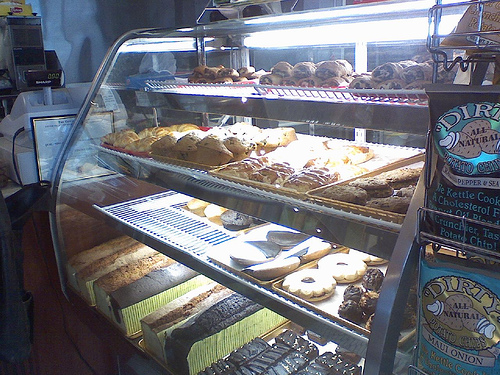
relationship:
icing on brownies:
[278, 340, 316, 372] [282, 332, 317, 359]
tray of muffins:
[156, 119, 304, 173] [149, 120, 298, 170]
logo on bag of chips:
[412, 253, 497, 374] [411, 250, 498, 364]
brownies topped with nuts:
[282, 332, 317, 359] [284, 327, 357, 373]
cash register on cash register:
[0, 68, 144, 185] [0, 68, 144, 185]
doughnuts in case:
[71, 64, 451, 372] [36, 3, 483, 364]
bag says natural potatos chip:
[425, 92, 499, 248] [434, 105, 499, 177]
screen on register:
[22, 66, 65, 90] [0, 68, 144, 185]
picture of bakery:
[1, 1, 499, 374] [71, 64, 451, 372]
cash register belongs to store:
[0, 68, 144, 185] [1, 1, 499, 374]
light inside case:
[229, 17, 469, 54] [36, 3, 483, 364]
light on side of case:
[123, 30, 229, 55] [36, 3, 483, 364]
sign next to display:
[28, 108, 124, 188] [36, 3, 483, 364]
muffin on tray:
[195, 136, 230, 167] [156, 119, 304, 173]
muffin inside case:
[195, 136, 230, 167] [36, 3, 483, 364]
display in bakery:
[36, 3, 483, 364] [1, 1, 499, 374]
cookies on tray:
[281, 267, 338, 301] [272, 246, 422, 343]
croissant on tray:
[105, 129, 136, 146] [99, 113, 214, 158]